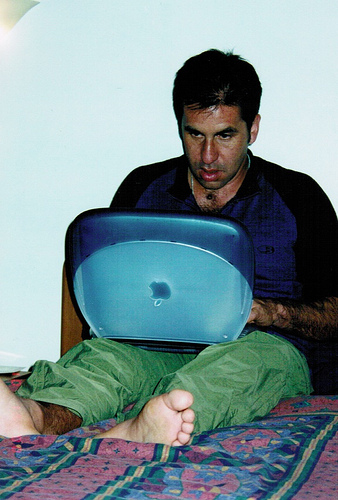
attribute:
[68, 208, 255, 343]
laptop — blue, old, gray, apple brand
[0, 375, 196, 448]
feet — bare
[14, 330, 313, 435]
pants — green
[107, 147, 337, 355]
shirt — black, blue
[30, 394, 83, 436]
leg — hairy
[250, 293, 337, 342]
arm — hairy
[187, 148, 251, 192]
necklace — silver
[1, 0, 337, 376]
wall — plain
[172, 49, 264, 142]
hair — black, dark, short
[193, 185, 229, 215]
chest — hairy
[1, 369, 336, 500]
bedspread — multicolored